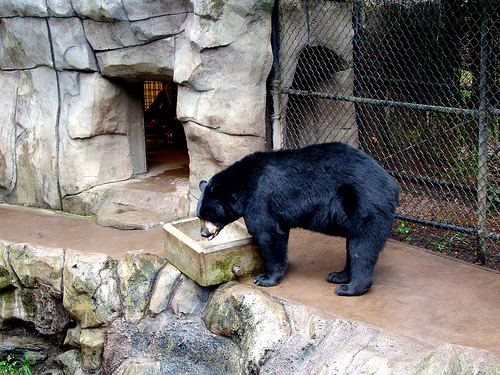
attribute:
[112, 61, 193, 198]
cave — open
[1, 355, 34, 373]
bush — green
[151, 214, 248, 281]
bin — white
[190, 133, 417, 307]
bear — black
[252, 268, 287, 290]
paw — large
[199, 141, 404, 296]
bear — black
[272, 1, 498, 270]
fence — mesh, chain-link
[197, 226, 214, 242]
nose — brown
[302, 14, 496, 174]
fence — chain-link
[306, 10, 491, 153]
fence — chain-link